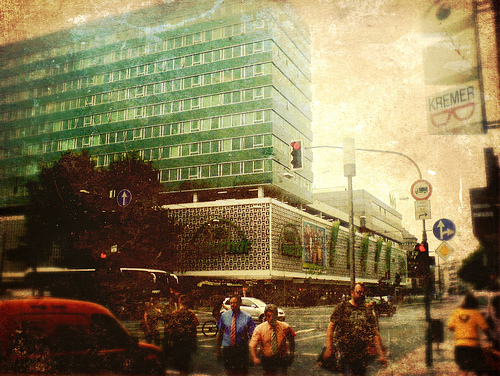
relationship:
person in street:
[140, 297, 164, 344] [120, 293, 465, 376]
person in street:
[164, 291, 200, 374] [120, 293, 465, 376]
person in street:
[213, 294, 255, 375] [120, 293, 465, 376]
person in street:
[250, 301, 297, 374] [120, 293, 465, 376]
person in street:
[321, 281, 389, 374] [120, 293, 465, 376]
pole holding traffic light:
[303, 143, 432, 319] [290, 139, 303, 171]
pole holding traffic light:
[303, 143, 432, 319] [415, 242, 429, 276]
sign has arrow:
[431, 217, 457, 242] [446, 226, 454, 236]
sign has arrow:
[431, 217, 457, 242] [436, 217, 446, 230]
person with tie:
[213, 294, 255, 375] [229, 312, 237, 347]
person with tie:
[250, 301, 297, 374] [270, 325, 280, 360]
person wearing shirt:
[213, 294, 255, 375] [217, 308, 256, 346]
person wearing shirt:
[250, 301, 297, 374] [250, 320, 297, 357]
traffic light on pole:
[415, 242, 429, 276] [303, 143, 432, 319]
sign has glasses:
[425, 80, 484, 135] [430, 101, 474, 128]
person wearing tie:
[213, 294, 255, 375] [229, 312, 237, 347]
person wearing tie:
[250, 301, 297, 374] [270, 325, 280, 360]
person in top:
[321, 281, 389, 374] [330, 299, 380, 362]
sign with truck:
[409, 178, 434, 201] [413, 185, 431, 195]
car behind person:
[220, 293, 285, 329] [213, 294, 255, 375]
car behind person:
[220, 293, 285, 329] [250, 301, 297, 374]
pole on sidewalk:
[422, 270, 434, 367] [376, 339, 500, 374]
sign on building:
[300, 215, 328, 271] [3, 2, 313, 305]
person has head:
[213, 294, 255, 375] [225, 292, 242, 312]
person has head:
[250, 301, 297, 374] [263, 299, 279, 327]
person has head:
[321, 281, 389, 374] [351, 279, 367, 305]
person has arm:
[213, 294, 255, 375] [213, 315, 223, 359]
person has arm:
[250, 301, 297, 374] [248, 325, 260, 364]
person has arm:
[250, 301, 297, 374] [282, 322, 297, 361]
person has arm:
[321, 281, 389, 374] [322, 301, 344, 360]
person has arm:
[321, 281, 389, 374] [370, 306, 389, 368]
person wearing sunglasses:
[321, 281, 389, 374] [354, 288, 368, 296]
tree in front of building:
[16, 145, 183, 307] [3, 2, 313, 305]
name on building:
[186, 233, 254, 261] [3, 2, 313, 305]